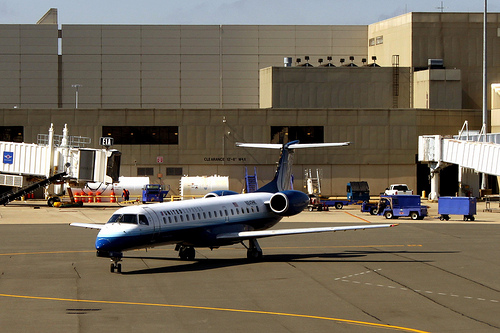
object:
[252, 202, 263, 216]
window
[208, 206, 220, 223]
window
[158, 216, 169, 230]
window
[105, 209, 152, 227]
window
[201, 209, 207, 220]
window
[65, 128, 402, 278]
plane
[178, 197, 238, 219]
window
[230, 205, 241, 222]
window